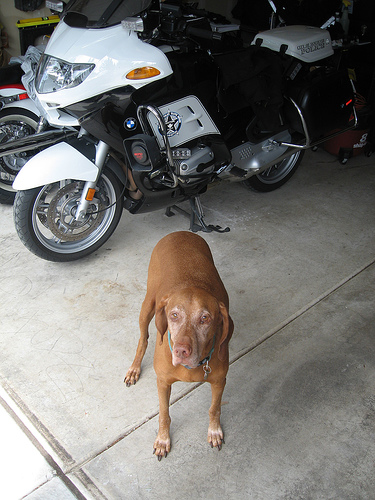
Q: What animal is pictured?
A: A dog.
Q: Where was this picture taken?
A: A garage.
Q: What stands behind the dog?
A: A white motorcycle.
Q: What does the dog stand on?
A: Cement.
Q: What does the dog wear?
A: A green collar.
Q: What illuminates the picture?
A: Natural sunlight.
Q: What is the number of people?
A: Zero.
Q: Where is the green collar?
A: On the dog.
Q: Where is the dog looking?
A: Up at the camera.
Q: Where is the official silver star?
A: On the motorcycle.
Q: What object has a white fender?
A: Motorcycle.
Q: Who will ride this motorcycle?
A: Police officer.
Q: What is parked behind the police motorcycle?
A: Another motorcycle.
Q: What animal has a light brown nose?
A: Dog.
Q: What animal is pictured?
A: A dog.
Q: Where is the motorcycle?
A: Behind the dog.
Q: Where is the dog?
A: On pavement.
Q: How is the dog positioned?
A: Standing.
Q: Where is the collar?
A: Around the dog's neck.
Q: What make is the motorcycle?
A: BMW.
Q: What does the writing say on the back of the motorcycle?
A: POLICE.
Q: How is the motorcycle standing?
A: A motorcycle stand.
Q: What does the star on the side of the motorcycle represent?
A: It is police issued.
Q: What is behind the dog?
A: Bike.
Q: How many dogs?
A: 1.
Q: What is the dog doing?
A: Standing.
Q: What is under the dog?
A: Cement.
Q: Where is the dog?
A: Garage.